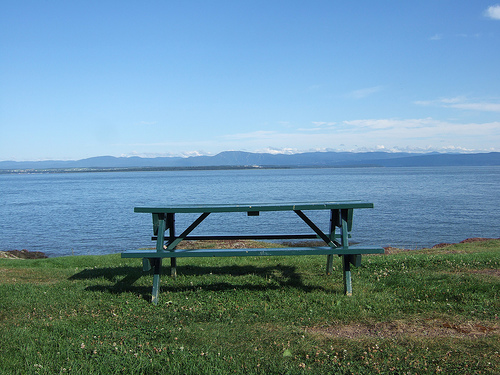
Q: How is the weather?
A: It is clear.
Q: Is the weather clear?
A: Yes, it is clear.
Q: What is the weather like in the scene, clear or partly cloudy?
A: It is clear.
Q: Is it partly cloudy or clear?
A: It is clear.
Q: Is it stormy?
A: No, it is clear.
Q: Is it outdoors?
A: Yes, it is outdoors.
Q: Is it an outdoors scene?
A: Yes, it is outdoors.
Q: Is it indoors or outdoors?
A: It is outdoors.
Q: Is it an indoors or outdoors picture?
A: It is outdoors.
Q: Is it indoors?
A: No, it is outdoors.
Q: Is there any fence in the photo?
A: No, there are no fences.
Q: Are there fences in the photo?
A: No, there are no fences.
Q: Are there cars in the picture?
A: No, there are no cars.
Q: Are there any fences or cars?
A: No, there are no cars or fences.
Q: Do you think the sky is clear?
A: Yes, the sky is clear.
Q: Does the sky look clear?
A: Yes, the sky is clear.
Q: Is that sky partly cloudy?
A: No, the sky is clear.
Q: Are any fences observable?
A: No, there are no fences.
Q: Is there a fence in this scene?
A: No, there are no fences.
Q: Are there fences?
A: No, there are no fences.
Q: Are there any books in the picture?
A: No, there are no books.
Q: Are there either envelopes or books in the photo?
A: No, there are no books or envelopes.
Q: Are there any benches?
A: Yes, there is a bench.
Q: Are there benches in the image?
A: Yes, there is a bench.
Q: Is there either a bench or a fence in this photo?
A: Yes, there is a bench.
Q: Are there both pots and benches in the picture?
A: No, there is a bench but no pots.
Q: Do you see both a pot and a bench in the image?
A: No, there is a bench but no pots.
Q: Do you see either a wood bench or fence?
A: Yes, there is a wood bench.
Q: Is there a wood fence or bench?
A: Yes, there is a wood bench.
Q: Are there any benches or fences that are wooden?
A: Yes, the bench is wooden.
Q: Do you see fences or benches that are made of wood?
A: Yes, the bench is made of wood.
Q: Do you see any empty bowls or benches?
A: Yes, there is an empty bench.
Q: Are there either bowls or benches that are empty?
A: Yes, the bench is empty.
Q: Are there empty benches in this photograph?
A: Yes, there is an empty bench.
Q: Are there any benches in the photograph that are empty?
A: Yes, there is a bench that is empty.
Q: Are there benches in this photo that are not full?
A: Yes, there is a empty bench.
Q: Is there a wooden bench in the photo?
A: Yes, there is a wood bench.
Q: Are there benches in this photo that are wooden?
A: Yes, there is a bench that is wooden.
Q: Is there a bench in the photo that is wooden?
A: Yes, there is a bench that is wooden.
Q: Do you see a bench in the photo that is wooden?
A: Yes, there is a bench that is wooden.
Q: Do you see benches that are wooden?
A: Yes, there is a bench that is wooden.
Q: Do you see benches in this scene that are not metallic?
A: Yes, there is a wooden bench.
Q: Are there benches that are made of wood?
A: Yes, there is a bench that is made of wood.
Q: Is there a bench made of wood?
A: Yes, there is a bench that is made of wood.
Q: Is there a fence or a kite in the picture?
A: No, there are no fences or kites.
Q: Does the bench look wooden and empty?
A: Yes, the bench is wooden and empty.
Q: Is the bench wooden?
A: Yes, the bench is wooden.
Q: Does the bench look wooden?
A: Yes, the bench is wooden.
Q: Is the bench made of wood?
A: Yes, the bench is made of wood.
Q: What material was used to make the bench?
A: The bench is made of wood.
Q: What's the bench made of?
A: The bench is made of wood.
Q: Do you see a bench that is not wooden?
A: No, there is a bench but it is wooden.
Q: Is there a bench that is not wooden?
A: No, there is a bench but it is wooden.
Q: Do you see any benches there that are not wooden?
A: No, there is a bench but it is wooden.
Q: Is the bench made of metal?
A: No, the bench is made of wood.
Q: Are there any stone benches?
A: No, there is a bench but it is made of wood.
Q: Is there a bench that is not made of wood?
A: No, there is a bench but it is made of wood.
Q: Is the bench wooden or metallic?
A: The bench is wooden.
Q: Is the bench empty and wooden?
A: Yes, the bench is empty and wooden.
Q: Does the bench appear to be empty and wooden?
A: Yes, the bench is empty and wooden.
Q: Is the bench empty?
A: Yes, the bench is empty.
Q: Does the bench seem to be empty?
A: Yes, the bench is empty.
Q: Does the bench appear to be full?
A: No, the bench is empty.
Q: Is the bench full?
A: No, the bench is empty.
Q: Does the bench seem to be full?
A: No, the bench is empty.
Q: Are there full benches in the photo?
A: No, there is a bench but it is empty.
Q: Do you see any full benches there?
A: No, there is a bench but it is empty.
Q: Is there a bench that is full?
A: No, there is a bench but it is empty.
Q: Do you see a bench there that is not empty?
A: No, there is a bench but it is empty.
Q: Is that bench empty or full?
A: The bench is empty.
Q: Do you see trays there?
A: No, there are no trays.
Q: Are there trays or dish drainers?
A: No, there are no trays or dish drainers.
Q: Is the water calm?
A: Yes, the water is calm.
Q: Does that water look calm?
A: Yes, the water is calm.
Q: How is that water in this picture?
A: The water is calm.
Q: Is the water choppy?
A: No, the water is calm.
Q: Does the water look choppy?
A: No, the water is calm.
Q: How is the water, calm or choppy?
A: The water is calm.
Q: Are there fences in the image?
A: No, there are no fences.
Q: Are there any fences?
A: No, there are no fences.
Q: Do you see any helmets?
A: No, there are no helmets.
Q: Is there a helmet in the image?
A: No, there are no helmets.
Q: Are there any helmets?
A: No, there are no helmets.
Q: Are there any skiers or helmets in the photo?
A: No, there are no helmets or skiers.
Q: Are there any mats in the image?
A: No, there are no mats.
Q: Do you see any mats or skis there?
A: No, there are no mats or skis.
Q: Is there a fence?
A: No, there are no fences.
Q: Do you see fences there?
A: No, there are no fences.